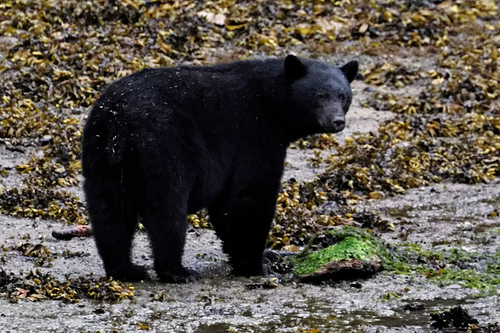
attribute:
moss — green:
[305, 237, 368, 276]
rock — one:
[289, 231, 385, 283]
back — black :
[117, 68, 247, 119]